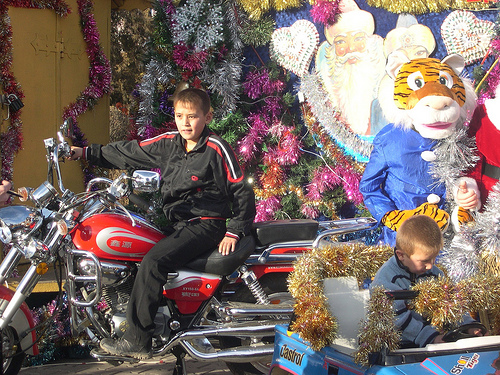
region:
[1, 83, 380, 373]
a boy sits on a motorcycle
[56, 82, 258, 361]
boy wears a red and black jacket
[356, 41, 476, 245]
a person in a tiger outfit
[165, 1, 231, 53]
a large decorative snowflake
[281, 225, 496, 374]
gold and silver tinsel surrounds a boy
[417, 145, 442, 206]
white pompoms on a blue jacket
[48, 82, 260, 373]
boy has short brown hair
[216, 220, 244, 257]
red and white striped cuff around a wrist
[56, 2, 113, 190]
strand of pink tinsel on a wall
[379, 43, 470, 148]
head of a tiger outfit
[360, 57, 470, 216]
The tiger mascot.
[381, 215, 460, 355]
The boy sitting on the ride.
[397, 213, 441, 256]
The boys blonde hair.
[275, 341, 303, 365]
The castrol sign on the ride.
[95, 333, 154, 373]
The boys black sneaker.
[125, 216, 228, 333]
The boys black pants.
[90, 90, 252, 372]
The boy sitting on the motorcycle.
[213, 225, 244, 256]
The boys left hand.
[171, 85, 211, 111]
The boys brown hair.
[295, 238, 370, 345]
Garland around the ride.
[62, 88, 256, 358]
A kid sitting down.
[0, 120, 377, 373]
A silver and red motorcycle.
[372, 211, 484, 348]
A kid with blonde hair.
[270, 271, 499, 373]
A blue kids car.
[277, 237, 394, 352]
Gold colored christmas tinsel.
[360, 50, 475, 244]
A person in a tiger costume.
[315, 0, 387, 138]
A picture of santa.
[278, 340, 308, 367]
Black lettering on blue.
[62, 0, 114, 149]
Pink and green tinsel.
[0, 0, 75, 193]
Red and silver tinsel.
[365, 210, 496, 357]
A young boy in the foreground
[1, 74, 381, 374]
Young boy is on a motorcycle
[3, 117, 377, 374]
A motorcycle in the foreground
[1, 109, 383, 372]
The motorcycle is red and silver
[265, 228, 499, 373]
A toy car in the foreground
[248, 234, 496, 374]
The toy car is light blue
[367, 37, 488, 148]
The head of a toy tiger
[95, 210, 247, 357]
Young boy is wearing black pants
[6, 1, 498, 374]
Photo was taken in the daytime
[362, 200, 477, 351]
boy has blonde hair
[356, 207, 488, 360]
boy has blue jacket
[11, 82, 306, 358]
girl sits in motorcycle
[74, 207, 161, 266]
tank of motorcycle is red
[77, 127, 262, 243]
the jacket is black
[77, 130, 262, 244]
jacket is red and white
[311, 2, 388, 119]
the picture of Santa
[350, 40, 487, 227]
a big plush of a tiger